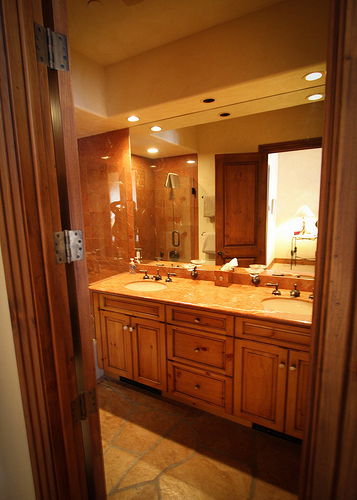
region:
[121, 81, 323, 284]
mirror on wall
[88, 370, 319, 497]
tile on floor of bathroom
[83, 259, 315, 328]
his and her sink in bathroom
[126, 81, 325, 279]
lamp in mirror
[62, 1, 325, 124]
lights on celling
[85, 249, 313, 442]
wood cabinet under sink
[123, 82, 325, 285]
door image in mirror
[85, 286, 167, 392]
knob on wood cabinet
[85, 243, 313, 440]
draws under his/her sink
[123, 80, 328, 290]
towel hanging on glass door image in mirror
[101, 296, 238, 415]
the drawers are closed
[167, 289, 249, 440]
the drawers are closed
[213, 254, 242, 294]
tissue in a brown box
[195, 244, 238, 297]
tissue in a brown box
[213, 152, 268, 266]
Small brown door in the mirror.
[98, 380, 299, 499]
Orange tiled floor with grey lines through it.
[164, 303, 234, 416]
A large, medium and small drawer under the counter.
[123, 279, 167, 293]
Sink to the left of another.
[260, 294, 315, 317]
Sink on the right.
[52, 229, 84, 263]
Top silver hinge of a door.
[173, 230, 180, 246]
Silver handle on a clear shower door.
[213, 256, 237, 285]
A mostly orange tissue box with white tissues in it on the counter.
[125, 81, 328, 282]
A very large mirror above two sinks and a counter.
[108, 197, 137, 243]
Reflection of a person in the shower door.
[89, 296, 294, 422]
brown, wooden drawers and cabinets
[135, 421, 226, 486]
the floor is tan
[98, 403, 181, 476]
the floor is tan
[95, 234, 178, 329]
sink on the left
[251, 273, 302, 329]
sink on the right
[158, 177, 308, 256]
reflection in the mirror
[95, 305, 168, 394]
cabinet on the left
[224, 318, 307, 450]
cabinet on the right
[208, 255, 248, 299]
box of white tissues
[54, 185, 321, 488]
the entry to the doorway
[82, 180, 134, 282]
wall of the bath tub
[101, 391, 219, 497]
the floor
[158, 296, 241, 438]
cabinet in the middle